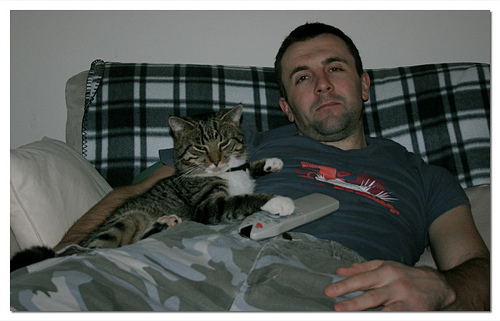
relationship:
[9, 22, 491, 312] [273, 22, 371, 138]
man has head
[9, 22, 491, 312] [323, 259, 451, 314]
man has hand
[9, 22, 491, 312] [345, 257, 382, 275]
man has finger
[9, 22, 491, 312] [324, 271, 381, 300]
man has finger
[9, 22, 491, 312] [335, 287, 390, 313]
man has finger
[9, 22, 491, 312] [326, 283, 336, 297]
man has finger nail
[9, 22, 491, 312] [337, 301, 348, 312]
man has finger nail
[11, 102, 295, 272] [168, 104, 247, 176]
cat has head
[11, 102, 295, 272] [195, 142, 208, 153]
cat has eye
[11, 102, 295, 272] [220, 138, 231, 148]
cat has eye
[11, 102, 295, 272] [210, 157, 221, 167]
cat has nose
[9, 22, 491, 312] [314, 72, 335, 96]
man has nose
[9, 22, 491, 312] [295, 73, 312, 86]
man has eye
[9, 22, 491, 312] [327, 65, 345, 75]
man has eye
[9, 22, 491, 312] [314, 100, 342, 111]
man has mouth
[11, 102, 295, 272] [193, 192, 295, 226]
cat has paw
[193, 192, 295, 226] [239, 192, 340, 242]
paw on remote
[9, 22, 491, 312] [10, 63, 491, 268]
man on couch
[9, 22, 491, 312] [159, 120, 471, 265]
man wearing shirt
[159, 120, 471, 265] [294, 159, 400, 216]
shirt has design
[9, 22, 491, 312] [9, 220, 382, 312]
man wearing pants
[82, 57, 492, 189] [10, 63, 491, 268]
blanket on couch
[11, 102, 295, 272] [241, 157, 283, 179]
cat has paw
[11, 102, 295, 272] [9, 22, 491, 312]
cat on top of man